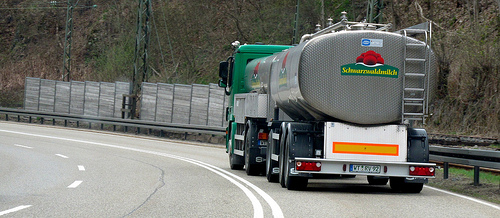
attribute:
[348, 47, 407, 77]
tag — Red 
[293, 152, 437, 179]
tag — Red , white 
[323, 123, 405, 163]
tag — Red and white 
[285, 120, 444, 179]
tag — Red and white 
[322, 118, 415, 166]
tag — Red and white 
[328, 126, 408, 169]
tag — Red and white 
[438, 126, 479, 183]
guard rail — METAL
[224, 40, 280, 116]
cabin — GREEN